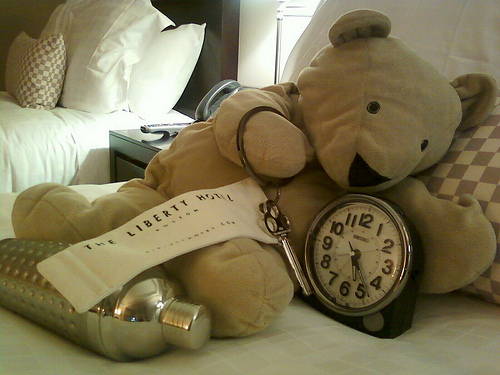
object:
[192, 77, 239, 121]
handset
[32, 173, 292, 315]
label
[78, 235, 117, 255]
word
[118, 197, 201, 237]
word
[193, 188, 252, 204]
word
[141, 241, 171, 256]
word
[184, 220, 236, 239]
word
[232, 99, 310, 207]
key ring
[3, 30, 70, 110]
pillow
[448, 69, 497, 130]
ear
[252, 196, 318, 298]
key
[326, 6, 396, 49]
ear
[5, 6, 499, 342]
bear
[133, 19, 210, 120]
pillow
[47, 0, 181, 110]
pillow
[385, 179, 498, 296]
hand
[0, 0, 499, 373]
bedroom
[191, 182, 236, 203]
hotel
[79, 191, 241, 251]
banner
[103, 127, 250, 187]
nightstand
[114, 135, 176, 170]
drawer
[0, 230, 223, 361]
liquor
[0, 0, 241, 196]
bed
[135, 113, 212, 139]
remote control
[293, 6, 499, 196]
head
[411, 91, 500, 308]
pillow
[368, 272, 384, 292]
number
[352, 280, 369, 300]
number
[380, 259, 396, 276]
number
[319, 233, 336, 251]
number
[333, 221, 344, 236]
number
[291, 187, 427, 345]
clock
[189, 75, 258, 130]
telephone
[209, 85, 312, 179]
wrist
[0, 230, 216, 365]
bottle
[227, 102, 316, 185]
hand